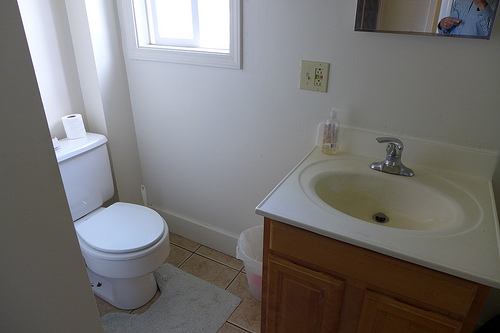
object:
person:
[431, 0, 498, 45]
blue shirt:
[432, 0, 495, 42]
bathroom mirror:
[351, 0, 498, 40]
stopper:
[374, 207, 389, 222]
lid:
[75, 201, 165, 253]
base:
[87, 262, 167, 318]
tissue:
[59, 109, 87, 139]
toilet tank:
[45, 127, 123, 228]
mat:
[87, 265, 257, 332]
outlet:
[299, 59, 331, 95]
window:
[128, 0, 235, 62]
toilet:
[36, 118, 181, 315]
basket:
[231, 224, 263, 301]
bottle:
[318, 108, 343, 157]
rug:
[99, 253, 244, 331]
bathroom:
[9, 1, 498, 328]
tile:
[192, 244, 243, 274]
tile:
[160, 242, 192, 268]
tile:
[212, 267, 259, 331]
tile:
[167, 251, 243, 289]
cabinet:
[354, 287, 490, 331]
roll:
[57, 109, 89, 145]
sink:
[311, 166, 480, 239]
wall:
[250, 46, 497, 93]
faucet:
[372, 133, 411, 173]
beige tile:
[176, 251, 242, 294]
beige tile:
[157, 238, 193, 277]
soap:
[320, 105, 343, 155]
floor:
[89, 230, 271, 330]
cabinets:
[261, 253, 352, 329]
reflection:
[357, 1, 490, 38]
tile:
[157, 230, 206, 256]